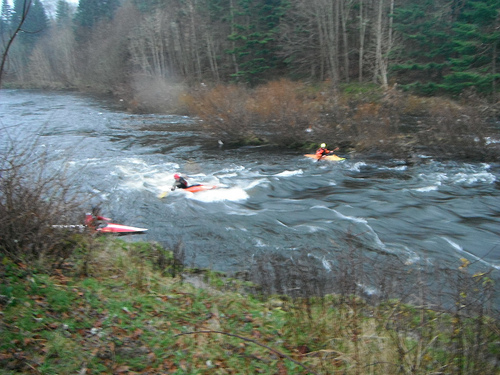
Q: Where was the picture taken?
A: It was taken at the river.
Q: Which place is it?
A: It is a river.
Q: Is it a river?
A: Yes, it is a river.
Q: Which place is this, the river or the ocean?
A: It is the river.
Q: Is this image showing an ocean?
A: No, the picture is showing a river.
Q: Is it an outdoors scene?
A: Yes, it is outdoors.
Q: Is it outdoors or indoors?
A: It is outdoors.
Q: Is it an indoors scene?
A: No, it is outdoors.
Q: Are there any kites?
A: No, there are no kites.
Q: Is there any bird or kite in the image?
A: No, there are no kites or birds.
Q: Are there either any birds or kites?
A: No, there are no kites or birds.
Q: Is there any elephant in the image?
A: No, there are no elephants.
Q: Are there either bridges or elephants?
A: No, there are no elephants or bridges.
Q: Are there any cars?
A: No, there are no cars.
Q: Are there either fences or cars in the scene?
A: No, there are no cars or fences.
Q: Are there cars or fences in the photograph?
A: No, there are no cars or fences.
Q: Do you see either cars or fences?
A: No, there are no cars or fences.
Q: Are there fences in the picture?
A: No, there are no fences.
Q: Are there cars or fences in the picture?
A: No, there are no fences or cars.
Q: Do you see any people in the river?
A: Yes, there is a person in the river.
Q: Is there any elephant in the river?
A: No, there is a person in the river.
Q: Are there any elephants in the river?
A: No, there is a person in the river.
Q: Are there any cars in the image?
A: No, there are no cars.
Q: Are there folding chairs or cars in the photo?
A: No, there are no cars or folding chairs.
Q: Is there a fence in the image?
A: No, there are no fences.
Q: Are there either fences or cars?
A: No, there are no fences or cars.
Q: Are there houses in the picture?
A: No, there are no houses.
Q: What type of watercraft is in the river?
A: The watercraft is a canoe.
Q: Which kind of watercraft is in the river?
A: The watercraft is a canoe.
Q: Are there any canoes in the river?
A: Yes, there is a canoe in the river.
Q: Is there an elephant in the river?
A: No, there is a canoe in the river.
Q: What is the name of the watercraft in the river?
A: The watercraft is a canoe.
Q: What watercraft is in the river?
A: The watercraft is a canoe.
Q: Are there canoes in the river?
A: Yes, there is a canoe in the river.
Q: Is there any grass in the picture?
A: Yes, there is grass.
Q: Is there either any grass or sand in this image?
A: Yes, there is grass.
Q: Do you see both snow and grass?
A: No, there is grass but no snow.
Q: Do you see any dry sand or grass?
A: Yes, there is dry grass.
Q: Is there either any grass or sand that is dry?
A: Yes, the grass is dry.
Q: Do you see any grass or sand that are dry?
A: Yes, the grass is dry.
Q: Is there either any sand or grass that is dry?
A: Yes, the grass is dry.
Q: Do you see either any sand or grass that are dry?
A: Yes, the grass is dry.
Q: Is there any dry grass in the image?
A: Yes, there is dry grass.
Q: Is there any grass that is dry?
A: Yes, there is grass that is dry.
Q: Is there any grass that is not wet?
A: Yes, there is dry grass.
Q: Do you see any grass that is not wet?
A: Yes, there is dry grass.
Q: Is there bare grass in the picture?
A: Yes, there is bare grass.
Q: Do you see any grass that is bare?
A: Yes, there is grass that is bare.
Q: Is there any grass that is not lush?
A: Yes, there is bare grass.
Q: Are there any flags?
A: No, there are no flags.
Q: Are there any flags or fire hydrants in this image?
A: No, there are no flags or fire hydrants.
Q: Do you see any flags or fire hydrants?
A: No, there are no flags or fire hydrants.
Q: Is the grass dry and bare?
A: Yes, the grass is dry and bare.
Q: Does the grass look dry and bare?
A: Yes, the grass is dry and bare.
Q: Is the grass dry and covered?
A: No, the grass is dry but bare.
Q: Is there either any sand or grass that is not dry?
A: No, there is grass but it is dry.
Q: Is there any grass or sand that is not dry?
A: No, there is grass but it is dry.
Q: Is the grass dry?
A: Yes, the grass is dry.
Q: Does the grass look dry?
A: Yes, the grass is dry.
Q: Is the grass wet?
A: No, the grass is dry.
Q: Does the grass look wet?
A: No, the grass is dry.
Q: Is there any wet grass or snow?
A: No, there is grass but it is dry.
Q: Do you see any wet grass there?
A: No, there is grass but it is dry.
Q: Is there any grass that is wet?
A: No, there is grass but it is dry.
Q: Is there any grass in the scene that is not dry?
A: No, there is grass but it is dry.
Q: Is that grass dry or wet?
A: The grass is dry.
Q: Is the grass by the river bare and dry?
A: Yes, the grass is bare and dry.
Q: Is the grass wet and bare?
A: No, the grass is bare but dry.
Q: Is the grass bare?
A: Yes, the grass is bare.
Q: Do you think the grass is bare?
A: Yes, the grass is bare.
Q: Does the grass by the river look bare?
A: Yes, the grass is bare.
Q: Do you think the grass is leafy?
A: No, the grass is bare.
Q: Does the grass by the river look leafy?
A: No, the grass is bare.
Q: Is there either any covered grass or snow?
A: No, there is grass but it is bare.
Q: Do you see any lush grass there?
A: No, there is grass but it is bare.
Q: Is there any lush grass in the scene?
A: No, there is grass but it is bare.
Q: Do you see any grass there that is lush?
A: No, there is grass but it is bare.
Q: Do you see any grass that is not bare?
A: No, there is grass but it is bare.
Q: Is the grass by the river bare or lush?
A: The grass is bare.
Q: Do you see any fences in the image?
A: No, there are no fences.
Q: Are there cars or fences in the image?
A: No, there are no fences or cars.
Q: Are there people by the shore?
A: Yes, there is a person by the shore.